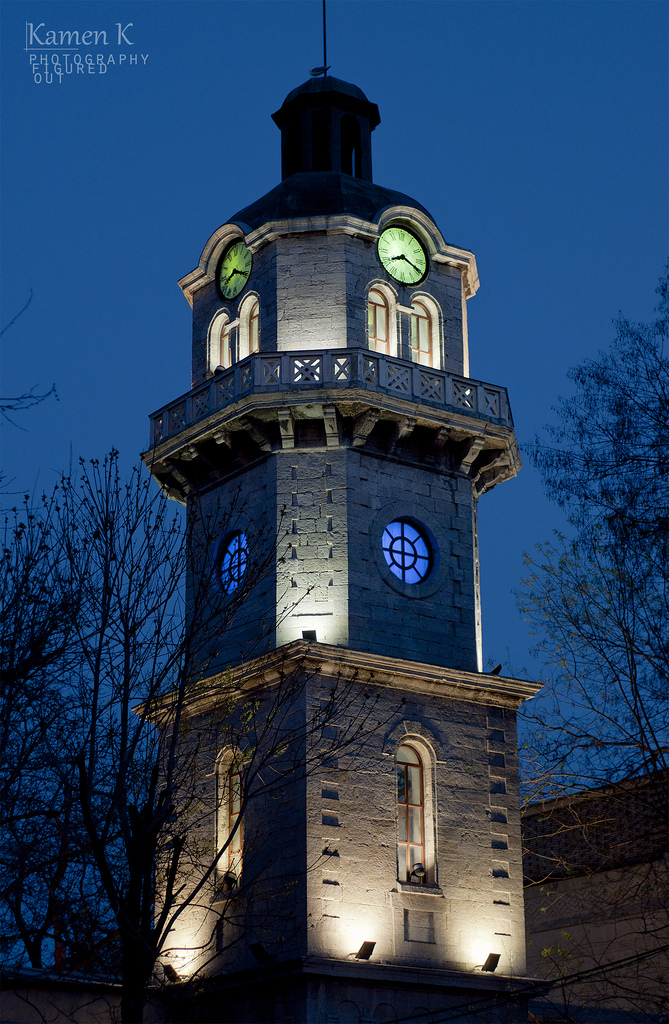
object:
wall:
[305, 655, 528, 986]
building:
[132, 0, 543, 1024]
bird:
[309, 65, 331, 78]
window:
[395, 733, 439, 894]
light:
[355, 941, 376, 961]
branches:
[157, 792, 250, 951]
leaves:
[104, 455, 109, 463]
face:
[378, 227, 426, 284]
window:
[365, 499, 448, 598]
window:
[217, 528, 250, 599]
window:
[236, 288, 260, 360]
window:
[206, 307, 232, 381]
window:
[364, 277, 400, 360]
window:
[409, 290, 444, 372]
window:
[213, 740, 247, 905]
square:
[323, 870, 339, 887]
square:
[322, 837, 341, 857]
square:
[322, 810, 339, 827]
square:
[322, 780, 339, 800]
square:
[320, 750, 339, 769]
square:
[492, 859, 509, 879]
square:
[492, 833, 509, 850]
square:
[489, 775, 506, 795]